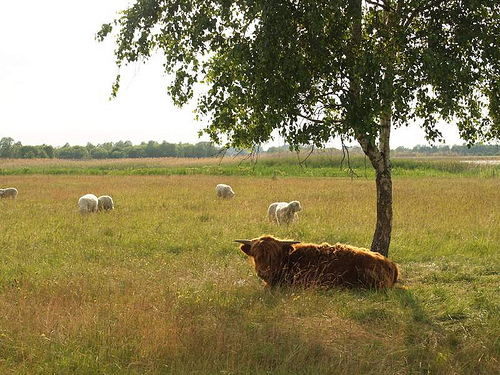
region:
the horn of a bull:
[232, 234, 252, 247]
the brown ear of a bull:
[238, 240, 251, 257]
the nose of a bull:
[253, 266, 275, 279]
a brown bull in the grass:
[231, 228, 406, 298]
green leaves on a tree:
[88, 0, 498, 157]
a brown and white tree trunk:
[349, 62, 403, 259]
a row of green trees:
[0, 134, 499, 161]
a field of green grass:
[1, 172, 496, 374]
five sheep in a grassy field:
[0, 181, 305, 223]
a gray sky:
[0, 1, 497, 146]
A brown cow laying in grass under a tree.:
[234, 233, 400, 297]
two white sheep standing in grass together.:
[76, 192, 116, 214]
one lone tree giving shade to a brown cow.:
[112, 2, 499, 237]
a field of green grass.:
[1, 221, 218, 354]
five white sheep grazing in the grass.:
[1, 175, 318, 232]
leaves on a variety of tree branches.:
[216, 60, 363, 140]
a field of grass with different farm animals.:
[2, 160, 496, 314]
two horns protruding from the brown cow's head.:
[235, 236, 299, 247]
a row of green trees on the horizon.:
[2, 139, 220, 157]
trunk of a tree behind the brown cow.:
[346, 91, 400, 249]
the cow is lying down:
[237, 225, 404, 303]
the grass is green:
[83, 260, 155, 307]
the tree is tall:
[267, 7, 447, 271]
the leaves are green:
[195, 30, 452, 113]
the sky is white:
[4, 18, 71, 125]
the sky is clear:
[2, 10, 77, 131]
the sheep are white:
[67, 189, 124, 224]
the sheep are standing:
[70, 188, 118, 215]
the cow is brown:
[230, 230, 406, 304]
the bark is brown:
[364, 139, 397, 260]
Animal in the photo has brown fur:
[225, 228, 438, 320]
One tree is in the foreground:
[81, 1, 498, 273]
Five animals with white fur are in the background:
[3, 159, 307, 239]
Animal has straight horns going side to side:
[229, 223, 420, 308]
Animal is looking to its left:
[255, 188, 325, 232]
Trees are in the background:
[7, 131, 225, 166]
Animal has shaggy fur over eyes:
[227, 222, 421, 309]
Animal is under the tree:
[173, 131, 453, 323]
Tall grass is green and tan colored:
[10, 178, 498, 374]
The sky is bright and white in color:
[0, 1, 205, 133]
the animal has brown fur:
[229, 233, 421, 305]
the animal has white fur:
[196, 178, 247, 203]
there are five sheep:
[0, 139, 342, 231]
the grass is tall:
[45, 258, 266, 370]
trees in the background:
[54, 116, 156, 163]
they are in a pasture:
[58, 178, 174, 263]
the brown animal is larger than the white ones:
[189, 174, 434, 371]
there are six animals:
[3, 178, 400, 331]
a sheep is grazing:
[194, 161, 262, 211]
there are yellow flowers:
[166, 277, 248, 329]